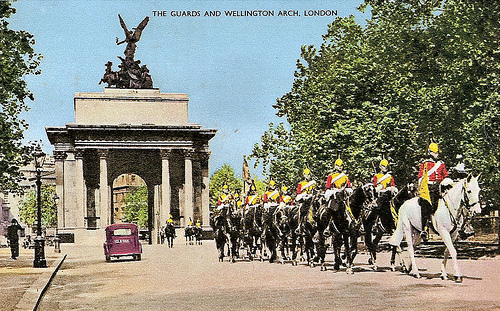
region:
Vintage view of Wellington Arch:
[41, 13, 216, 245]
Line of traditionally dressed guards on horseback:
[213, 138, 486, 287]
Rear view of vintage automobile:
[102, 220, 145, 262]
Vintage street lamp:
[14, 143, 66, 268]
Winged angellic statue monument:
[100, 13, 155, 90]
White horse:
[386, 170, 486, 285]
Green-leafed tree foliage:
[219, 19, 498, 141]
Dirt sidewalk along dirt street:
[1, 265, 299, 308]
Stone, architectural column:
[94, 145, 113, 229]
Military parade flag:
[238, 152, 255, 205]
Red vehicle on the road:
[97, 222, 142, 259]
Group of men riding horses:
[220, 138, 480, 287]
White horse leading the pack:
[385, 148, 480, 280]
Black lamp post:
[24, 142, 56, 269]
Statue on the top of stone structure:
[93, 8, 159, 92]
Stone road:
[51, 237, 499, 309]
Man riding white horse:
[419, 139, 445, 237]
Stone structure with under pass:
[50, 88, 213, 238]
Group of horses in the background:
[163, 207, 207, 256]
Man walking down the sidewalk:
[10, 216, 21, 256]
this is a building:
[74, 84, 194, 194]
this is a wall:
[76, 101, 146, 123]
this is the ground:
[149, 258, 215, 290]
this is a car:
[99, 218, 145, 278]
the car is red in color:
[111, 235, 148, 257]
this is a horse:
[443, 190, 476, 280]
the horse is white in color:
[397, 203, 417, 220]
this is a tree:
[311, 46, 402, 125]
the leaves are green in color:
[348, 50, 403, 106]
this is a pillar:
[186, 157, 198, 232]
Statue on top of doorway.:
[98, 11, 157, 92]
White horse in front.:
[387, 170, 484, 289]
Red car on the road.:
[102, 223, 145, 259]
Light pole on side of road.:
[31, 139, 47, 271]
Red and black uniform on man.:
[417, 141, 449, 235]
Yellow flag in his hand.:
[413, 158, 432, 209]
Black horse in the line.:
[314, 180, 380, 269]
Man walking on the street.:
[7, 216, 24, 259]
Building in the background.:
[113, 169, 150, 228]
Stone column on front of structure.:
[157, 152, 174, 227]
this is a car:
[105, 218, 146, 255]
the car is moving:
[93, 216, 141, 263]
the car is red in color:
[103, 225, 138, 257]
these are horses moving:
[217, 161, 483, 264]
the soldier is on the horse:
[408, 140, 445, 189]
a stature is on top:
[96, 10, 159, 85]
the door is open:
[106, 171, 151, 214]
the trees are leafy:
[333, 14, 486, 139]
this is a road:
[153, 250, 220, 307]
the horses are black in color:
[290, 197, 346, 245]